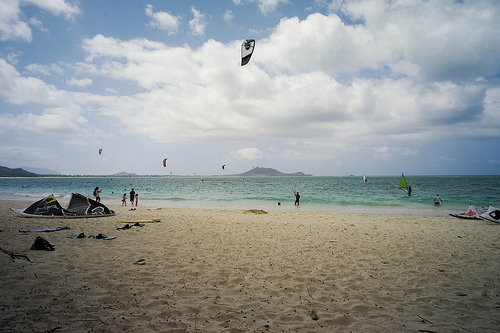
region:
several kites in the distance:
[77, 136, 251, 179]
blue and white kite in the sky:
[231, 36, 259, 71]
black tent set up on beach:
[22, 188, 119, 225]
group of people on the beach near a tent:
[87, 179, 158, 220]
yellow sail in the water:
[391, 171, 416, 195]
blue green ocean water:
[65, 168, 480, 211]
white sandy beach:
[133, 231, 461, 325]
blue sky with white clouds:
[39, 10, 480, 170]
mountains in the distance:
[2, 159, 330, 190]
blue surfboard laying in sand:
[16, 220, 84, 242]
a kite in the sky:
[226, 31, 266, 72]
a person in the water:
[285, 188, 307, 210]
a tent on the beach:
[3, 186, 125, 227]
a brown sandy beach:
[2, 194, 498, 330]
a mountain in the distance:
[229, 160, 319, 181]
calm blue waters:
[0, 171, 497, 221]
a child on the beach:
[116, 189, 131, 208]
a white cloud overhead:
[139, 1, 190, 38]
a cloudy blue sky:
[0, 0, 498, 179]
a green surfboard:
[394, 168, 414, 195]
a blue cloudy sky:
[1, 0, 498, 182]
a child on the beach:
[131, 190, 143, 208]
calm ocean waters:
[1, 170, 498, 214]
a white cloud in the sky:
[140, 2, 191, 42]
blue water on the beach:
[0, 174, 497, 211]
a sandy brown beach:
[6, 205, 497, 331]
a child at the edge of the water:
[131, 191, 145, 209]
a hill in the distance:
[228, 161, 314, 183]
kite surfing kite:
[240, 37, 254, 65]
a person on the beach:
[293, 191, 300, 206]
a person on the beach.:
[92, 186, 102, 202]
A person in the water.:
[433, 193, 441, 204]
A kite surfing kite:
[162, 156, 167, 167]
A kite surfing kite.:
[96, 146, 103, 154]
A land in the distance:
[0, 166, 357, 177]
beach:
[0, 191, 499, 331]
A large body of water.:
[1, 176, 498, 217]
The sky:
[0, 0, 498, 175]